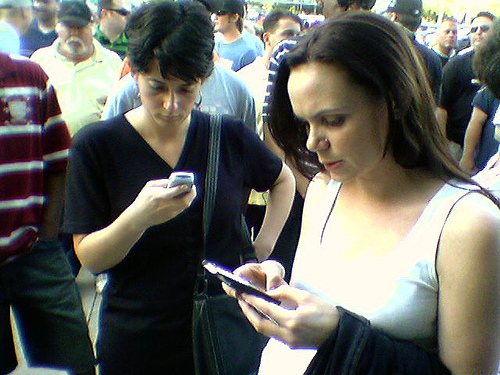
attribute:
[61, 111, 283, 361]
shirt — on woman, on train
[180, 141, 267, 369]
bag — on hand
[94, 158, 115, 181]
fabric — on train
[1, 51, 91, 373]
man — on shoulder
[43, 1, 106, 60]
hat — on shoulder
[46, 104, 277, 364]
shirt — on train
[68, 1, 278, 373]
woman — on shoulder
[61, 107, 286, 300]
shirt — on woman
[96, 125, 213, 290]
shirt — on train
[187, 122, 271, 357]
leather bag — on shoulder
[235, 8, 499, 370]
woman — holding a phone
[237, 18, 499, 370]
person — texting 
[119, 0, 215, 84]
hair — short, dark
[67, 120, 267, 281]
shirt — on train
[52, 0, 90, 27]
cap — black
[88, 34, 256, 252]
person — texting 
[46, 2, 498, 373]
woman — on shoulder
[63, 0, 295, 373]
person — texting 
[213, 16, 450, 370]
person — texting 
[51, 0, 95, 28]
hat — black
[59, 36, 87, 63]
facial hair — white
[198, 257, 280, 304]
phone — on hand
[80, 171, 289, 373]
fabric — black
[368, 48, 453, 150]
hair — on shoulder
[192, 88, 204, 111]
earring — on train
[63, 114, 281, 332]
shirt — black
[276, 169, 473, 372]
tank top — white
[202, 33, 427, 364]
woman — on hand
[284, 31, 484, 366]
person — texting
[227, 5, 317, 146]
shirt — white 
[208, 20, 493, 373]
person — texting 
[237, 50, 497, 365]
person — texting 